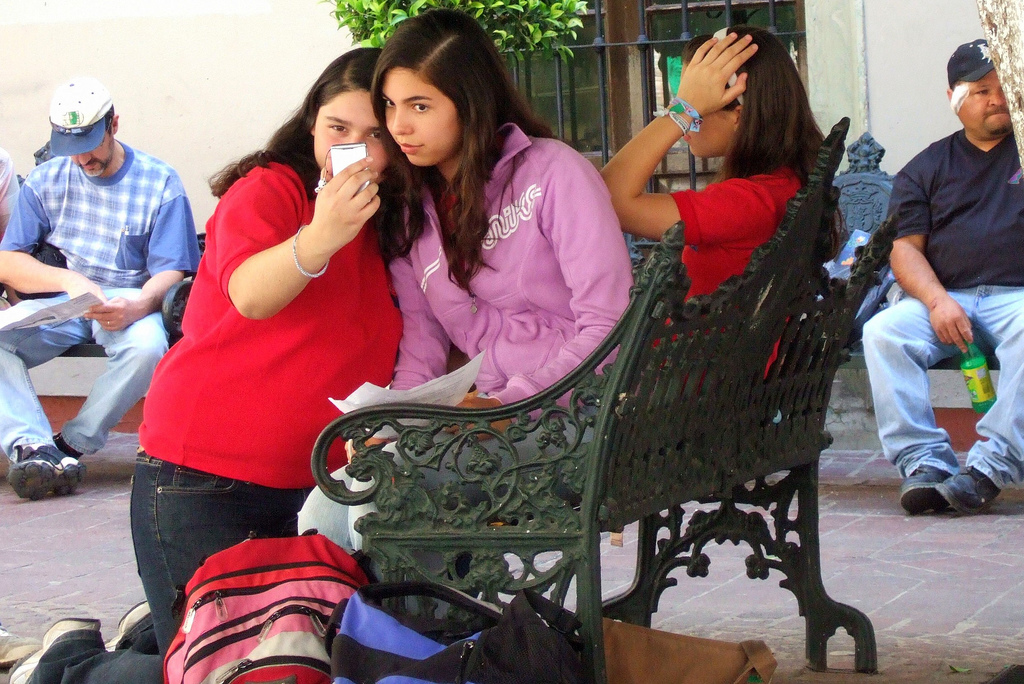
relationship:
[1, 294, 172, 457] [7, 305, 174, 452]
pair of jeans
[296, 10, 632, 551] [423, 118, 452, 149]
girl has cheek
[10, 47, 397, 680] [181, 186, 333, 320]
girl has arm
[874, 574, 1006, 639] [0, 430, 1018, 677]
stone in floor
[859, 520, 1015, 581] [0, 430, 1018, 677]
stone in floor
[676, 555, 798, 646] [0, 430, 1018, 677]
stone in floor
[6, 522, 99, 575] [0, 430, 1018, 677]
stone in floor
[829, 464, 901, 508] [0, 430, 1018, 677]
stone in floor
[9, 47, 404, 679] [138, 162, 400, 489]
girl wearing shirt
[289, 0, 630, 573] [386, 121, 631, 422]
girl wearing shirt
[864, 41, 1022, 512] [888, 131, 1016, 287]
man wearing shirt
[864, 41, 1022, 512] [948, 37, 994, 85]
man wearing hat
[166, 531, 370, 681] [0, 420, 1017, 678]
backpack on floor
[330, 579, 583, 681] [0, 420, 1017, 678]
backpack on floor